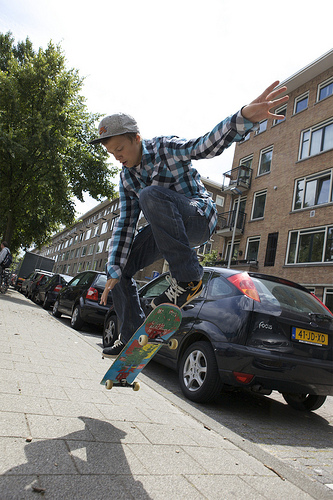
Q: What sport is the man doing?
A: Skateboarding.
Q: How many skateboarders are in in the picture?
A: One.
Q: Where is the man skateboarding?
A: On the sidewalk.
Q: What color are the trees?
A: Green.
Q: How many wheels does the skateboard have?
A: Four.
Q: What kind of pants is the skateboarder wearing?
A: Jeans.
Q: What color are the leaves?
A: Green.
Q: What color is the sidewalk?
A: Gray.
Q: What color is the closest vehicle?
A: Black.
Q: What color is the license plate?
A: Yellow.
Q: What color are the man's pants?
A: Blue.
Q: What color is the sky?
A: White.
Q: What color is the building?
A: Brown.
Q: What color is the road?
A: Gray.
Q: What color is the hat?
A: Gray.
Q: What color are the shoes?
A: Black.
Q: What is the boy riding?
A: A skateboard.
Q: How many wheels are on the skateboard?
A: Four.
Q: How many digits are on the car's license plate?
A: Six.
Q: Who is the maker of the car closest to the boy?
A: Ford.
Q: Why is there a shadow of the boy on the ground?
A: Because it's sunny out.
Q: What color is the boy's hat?
A: Gray.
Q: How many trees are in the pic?
A: One.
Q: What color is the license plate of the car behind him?
A: Yellow.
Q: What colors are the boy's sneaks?
A: Black and orange.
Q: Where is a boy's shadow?
A: On the ground.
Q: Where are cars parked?
A: On side of the street.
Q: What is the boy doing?
A: A trick on his skateboard.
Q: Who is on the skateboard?
A: A boy.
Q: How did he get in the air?
A: He jumped.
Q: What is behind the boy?
A: A car.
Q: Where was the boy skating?
A: On the sidewalk.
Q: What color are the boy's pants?
A: Blue.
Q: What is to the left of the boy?
A: A tree.